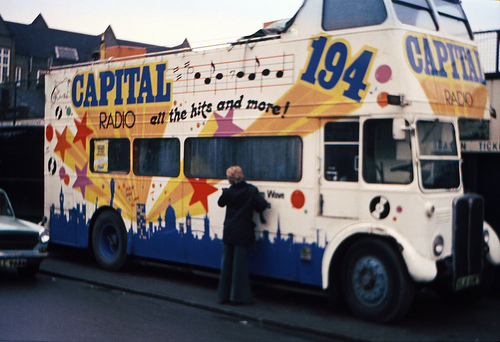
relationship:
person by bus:
[215, 161, 276, 313] [44, 0, 493, 322]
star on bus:
[181, 173, 216, 215] [260, 61, 377, 164]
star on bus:
[71, 162, 94, 194] [51, 54, 472, 334]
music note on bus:
[184, 62, 194, 87] [44, 0, 493, 322]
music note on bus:
[203, 55, 215, 86] [44, 0, 493, 322]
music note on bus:
[237, 46, 247, 76] [44, 0, 493, 322]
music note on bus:
[259, 65, 269, 95] [44, 0, 493, 322]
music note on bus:
[61, 79, 73, 99] [44, 0, 493, 322]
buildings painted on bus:
[43, 177, 328, 289] [44, 0, 493, 322]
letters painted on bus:
[69, 68, 169, 107] [44, 0, 493, 322]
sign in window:
[68, 98, 155, 182] [180, 107, 298, 177]